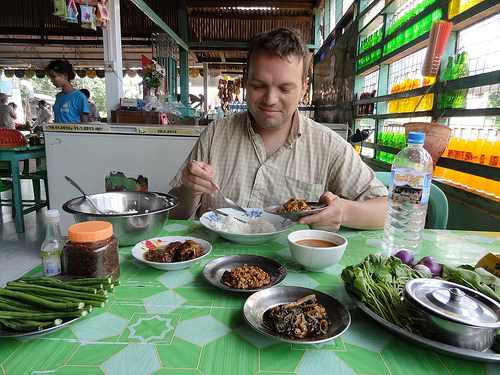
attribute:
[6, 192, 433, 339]
table — green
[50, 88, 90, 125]
shirt — blue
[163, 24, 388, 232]
man — white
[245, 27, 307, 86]
hair — dark brown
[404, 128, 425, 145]
cap — blue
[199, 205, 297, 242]
white bowl — blue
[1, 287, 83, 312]
bean — fresh cut, green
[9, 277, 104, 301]
bean — fresh cut, green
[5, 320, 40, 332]
bean — fresh cut, green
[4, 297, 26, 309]
bean — fresh cut, green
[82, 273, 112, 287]
bean — fresh cut, green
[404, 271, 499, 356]
dish — metal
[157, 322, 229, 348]
tablecloth — green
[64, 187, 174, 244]
bowl — metal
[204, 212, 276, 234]
rice — white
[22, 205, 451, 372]
table top — green, white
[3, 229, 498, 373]
table — large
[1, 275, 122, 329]
green beans — green 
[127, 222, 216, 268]
dish — white